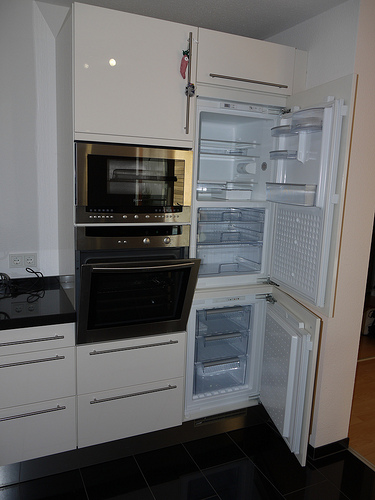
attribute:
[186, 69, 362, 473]
refrigerator — new, white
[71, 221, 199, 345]
oven — stainless steel, open, new, silver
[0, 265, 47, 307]
cord — tangled, black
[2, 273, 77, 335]
counter — black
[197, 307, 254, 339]
drawer — plastic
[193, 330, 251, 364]
drawer — plastic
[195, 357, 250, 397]
drawer — plastic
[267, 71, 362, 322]
door — open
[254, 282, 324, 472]
door — open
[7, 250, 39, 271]
socket — white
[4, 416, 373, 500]
floor — tiled, black, shiny, dark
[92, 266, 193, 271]
handle — silver, metal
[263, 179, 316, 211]
tray — clear, plastic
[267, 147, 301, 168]
tray — clear, plastic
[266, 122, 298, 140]
tray — clear, plastic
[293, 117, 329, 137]
tray — clear, plastic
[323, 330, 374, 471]
floor — wood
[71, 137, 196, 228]
microwave — silver, black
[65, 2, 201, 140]
cabinet — white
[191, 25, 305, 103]
cabinet — white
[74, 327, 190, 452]
cabinet — white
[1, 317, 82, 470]
cabinet — white